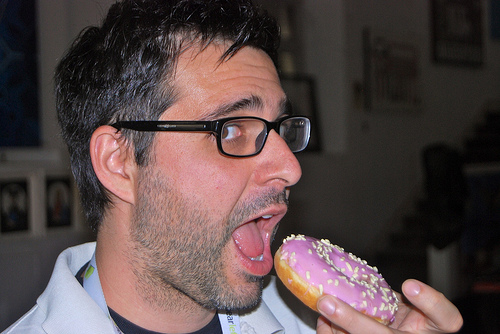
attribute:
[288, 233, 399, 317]
frosting — pink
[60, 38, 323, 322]
man — eating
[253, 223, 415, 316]
doughnut — glazed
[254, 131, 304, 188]
nose — pointed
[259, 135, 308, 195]
nose — pointed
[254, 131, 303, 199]
nose — pointed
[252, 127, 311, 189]
nose — pointed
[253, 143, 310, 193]
nose — pointed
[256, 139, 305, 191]
nose — pointed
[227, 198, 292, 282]
mouth — open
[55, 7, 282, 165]
hair — black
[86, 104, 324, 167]
glasses — black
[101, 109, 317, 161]
glasses — dark rimmed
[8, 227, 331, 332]
collar — white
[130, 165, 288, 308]
beard — scurffy